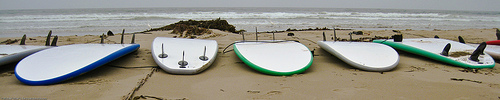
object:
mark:
[177, 56, 190, 70]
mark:
[157, 51, 170, 60]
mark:
[198, 53, 213, 63]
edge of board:
[12, 62, 74, 85]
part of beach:
[0, 1, 498, 100]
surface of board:
[13, 41, 139, 89]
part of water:
[0, 5, 499, 36]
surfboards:
[0, 43, 58, 68]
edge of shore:
[1, 27, 498, 42]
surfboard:
[228, 39, 312, 77]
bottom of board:
[148, 34, 220, 76]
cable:
[117, 62, 159, 100]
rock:
[147, 19, 241, 37]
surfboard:
[370, 37, 496, 69]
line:
[409, 60, 422, 76]